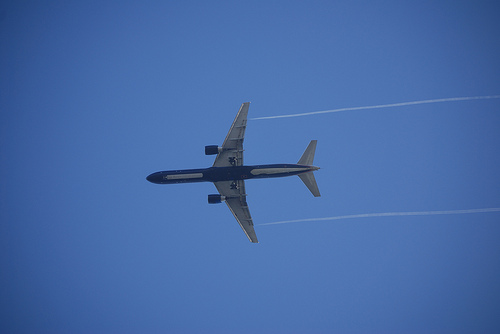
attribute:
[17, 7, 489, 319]
sky — clear, blue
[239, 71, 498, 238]
smoke — white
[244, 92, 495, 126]
smoke — white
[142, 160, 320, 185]
part — inner, plane, dark blue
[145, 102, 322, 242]
jet plane — overhead, jet 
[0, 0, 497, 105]
blue sky — clear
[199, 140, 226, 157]
exhauster — blue